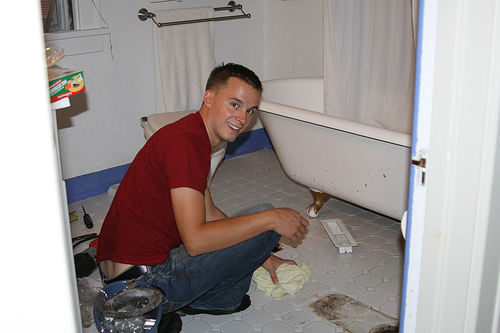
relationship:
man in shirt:
[91, 61, 309, 330] [99, 105, 212, 264]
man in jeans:
[91, 61, 309, 330] [68, 205, 287, 319]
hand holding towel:
[258, 248, 298, 281] [247, 259, 314, 303]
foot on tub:
[304, 186, 332, 222] [249, 72, 412, 235]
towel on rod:
[151, 6, 212, 118] [132, 6, 257, 32]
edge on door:
[396, 0, 430, 331] [399, 3, 494, 331]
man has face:
[91, 61, 309, 330] [202, 75, 264, 152]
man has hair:
[91, 61, 309, 330] [204, 59, 265, 99]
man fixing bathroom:
[91, 61, 309, 330] [53, 0, 497, 330]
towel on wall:
[151, 6, 212, 118] [0, 6, 357, 179]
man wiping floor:
[91, 61, 309, 330] [33, 139, 427, 329]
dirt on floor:
[306, 281, 407, 331] [33, 139, 427, 329]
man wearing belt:
[91, 61, 309, 330] [88, 264, 154, 284]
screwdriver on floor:
[76, 205, 96, 231] [33, 139, 427, 329]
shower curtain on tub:
[319, 2, 420, 139] [249, 72, 412, 235]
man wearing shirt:
[91, 61, 309, 330] [99, 105, 212, 264]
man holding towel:
[91, 61, 309, 330] [247, 259, 314, 303]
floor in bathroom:
[33, 139, 427, 329] [53, 0, 497, 330]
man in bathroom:
[91, 61, 309, 330] [53, 0, 497, 330]